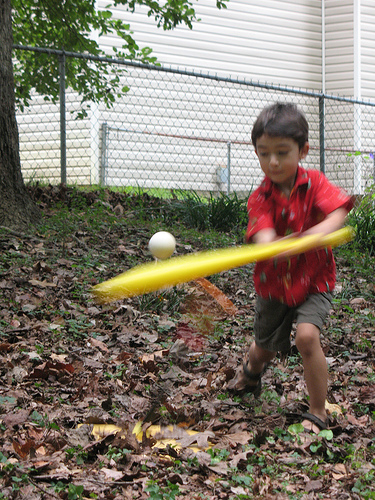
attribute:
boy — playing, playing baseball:
[232, 102, 354, 421]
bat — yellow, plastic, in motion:
[92, 225, 352, 301]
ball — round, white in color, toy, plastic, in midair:
[149, 230, 178, 262]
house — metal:
[11, 41, 373, 194]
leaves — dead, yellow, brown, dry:
[0, 258, 374, 499]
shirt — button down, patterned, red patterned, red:
[244, 163, 351, 304]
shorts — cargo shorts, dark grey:
[252, 296, 331, 354]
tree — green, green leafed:
[1, 0, 219, 224]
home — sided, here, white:
[14, 1, 373, 190]